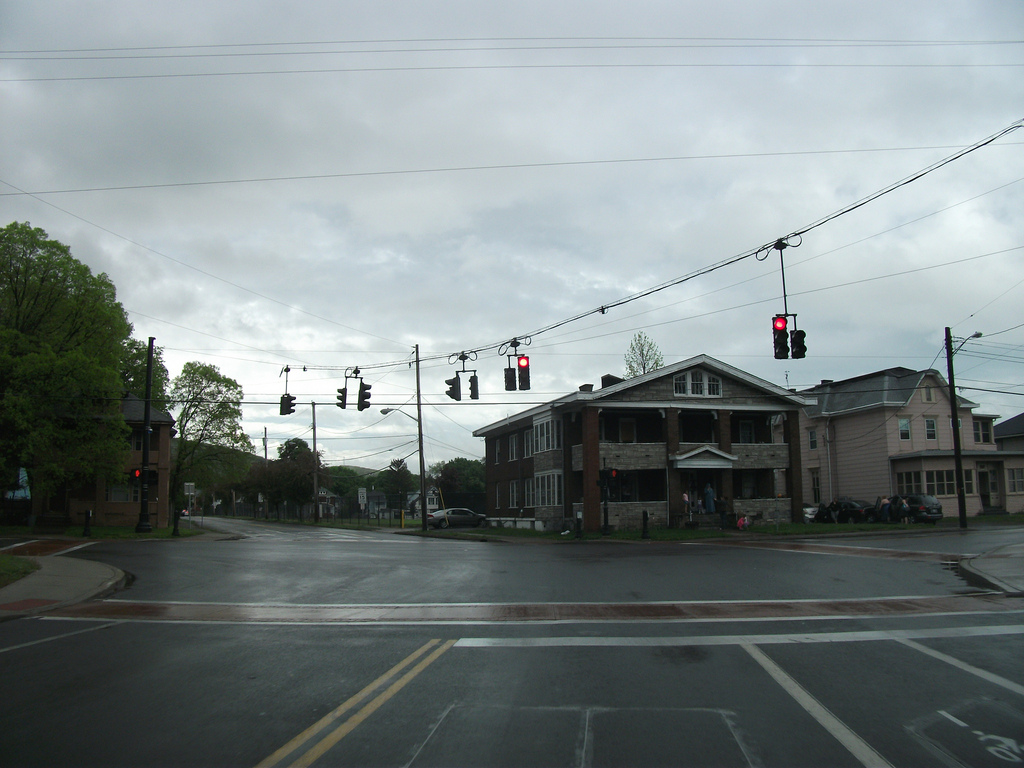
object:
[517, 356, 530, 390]
light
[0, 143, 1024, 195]
wire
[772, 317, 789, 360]
light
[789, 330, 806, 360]
light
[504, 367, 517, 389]
light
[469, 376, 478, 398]
light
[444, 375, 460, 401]
light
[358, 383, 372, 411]
light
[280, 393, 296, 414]
light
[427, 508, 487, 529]
car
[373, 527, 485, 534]
driveway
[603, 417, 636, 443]
window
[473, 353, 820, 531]
house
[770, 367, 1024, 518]
house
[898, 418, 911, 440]
window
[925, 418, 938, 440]
window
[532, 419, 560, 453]
window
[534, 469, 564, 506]
window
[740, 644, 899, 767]
line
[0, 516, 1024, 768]
street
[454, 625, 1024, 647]
line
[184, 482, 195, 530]
sign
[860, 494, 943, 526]
van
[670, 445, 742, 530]
porch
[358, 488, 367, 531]
sign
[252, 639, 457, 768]
line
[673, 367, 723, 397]
window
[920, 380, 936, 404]
window